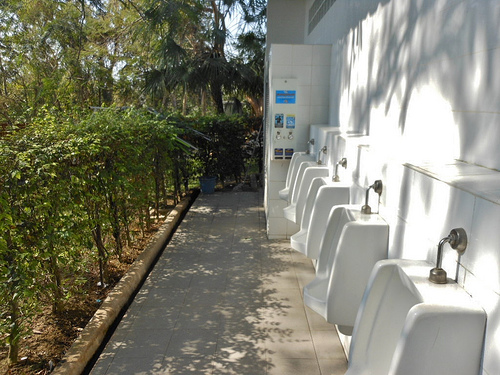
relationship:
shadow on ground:
[79, 188, 293, 373] [0, 182, 357, 374]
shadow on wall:
[321, 0, 499, 264] [328, 2, 499, 373]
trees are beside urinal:
[1, 101, 184, 365] [294, 198, 393, 328]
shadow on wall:
[79, 188, 293, 373] [328, 2, 499, 373]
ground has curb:
[0, 182, 357, 374] [44, 187, 198, 369]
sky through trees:
[1, 2, 263, 84] [4, 7, 260, 136]